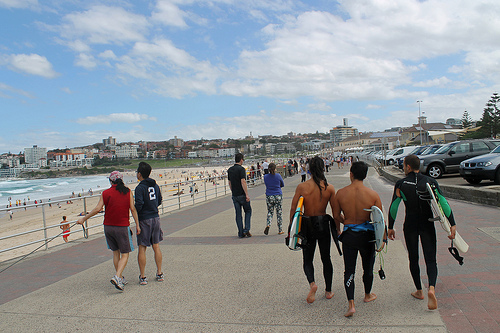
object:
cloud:
[217, 0, 497, 99]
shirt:
[99, 185, 133, 227]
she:
[75, 171, 143, 292]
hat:
[105, 170, 123, 184]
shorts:
[102, 223, 132, 254]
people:
[225, 152, 253, 239]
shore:
[1, 162, 288, 266]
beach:
[1, 166, 270, 264]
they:
[286, 154, 458, 318]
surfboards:
[285, 195, 307, 252]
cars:
[457, 142, 499, 187]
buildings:
[0, 134, 236, 175]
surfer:
[331, 159, 388, 319]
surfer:
[287, 153, 337, 305]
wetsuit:
[338, 223, 378, 301]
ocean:
[1, 178, 114, 213]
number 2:
[147, 185, 156, 204]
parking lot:
[370, 135, 498, 206]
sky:
[0, 1, 498, 148]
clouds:
[1, 2, 225, 98]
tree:
[479, 91, 499, 138]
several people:
[76, 152, 460, 321]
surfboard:
[363, 204, 388, 254]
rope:
[3, 221, 77, 293]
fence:
[2, 163, 282, 263]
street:
[0, 159, 498, 332]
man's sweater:
[133, 178, 165, 221]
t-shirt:
[224, 165, 246, 198]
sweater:
[262, 172, 285, 197]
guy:
[380, 155, 455, 313]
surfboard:
[416, 181, 470, 253]